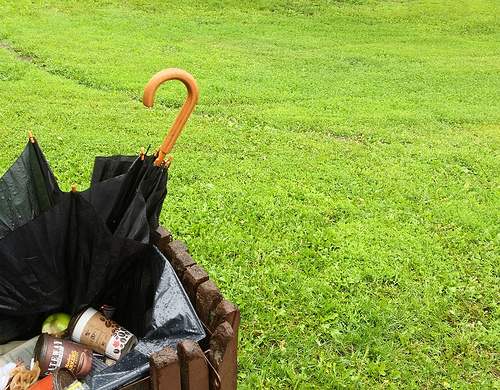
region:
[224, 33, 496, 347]
the grass is green and visible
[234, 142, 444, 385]
the grass is green and visible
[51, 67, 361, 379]
the grass is green and visible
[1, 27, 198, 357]
black umbrella with wooden handle in wooden trash bin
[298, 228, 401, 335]
patch of green grass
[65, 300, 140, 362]
empty cup of coffee in trash bin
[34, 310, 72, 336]
partially eaten green apple in trash bin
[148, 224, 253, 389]
corner of brown wooden trash bin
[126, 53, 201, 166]
brown wooden umbrella hook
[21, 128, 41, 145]
wood tip of umbrella spoke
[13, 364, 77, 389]
orange cup with brown lid in wooden trash bin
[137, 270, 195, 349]
black trash bag in brown wooden trash bin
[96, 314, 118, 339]
brown design on coffee cup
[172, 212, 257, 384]
edge of wood trash can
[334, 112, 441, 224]
neatly trimmed green grass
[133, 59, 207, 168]
wood handle of umbrella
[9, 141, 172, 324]
black material of umbrella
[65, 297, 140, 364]
paper cup in trash can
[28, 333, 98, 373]
coffee cup with lid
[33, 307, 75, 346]
green apple with bite missing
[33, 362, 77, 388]
orange cup in trash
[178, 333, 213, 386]
brown wood on trash can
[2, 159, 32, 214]
water drops on umbrella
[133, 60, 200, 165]
handle of an umbrella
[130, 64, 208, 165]
handle of umbrella is brown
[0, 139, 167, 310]
canopy of umbrella is fold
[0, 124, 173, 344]
canopy of umbrellas is black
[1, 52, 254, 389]
an umbrella on a trash can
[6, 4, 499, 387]
a trash can a green field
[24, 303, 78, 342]
an apple in the trash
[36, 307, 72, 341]
green apple is bitten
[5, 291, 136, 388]
trash in a trash can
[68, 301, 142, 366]
a coffee cup in the trash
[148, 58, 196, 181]
brown handle on umbrella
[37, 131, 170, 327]
umbrella is black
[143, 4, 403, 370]
grass is green and thick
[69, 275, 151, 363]
foam cup in bin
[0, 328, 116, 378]
brown cup in bin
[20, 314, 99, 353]
green apple in bin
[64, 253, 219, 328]
black bag in bin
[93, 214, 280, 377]
bin is wooden and brown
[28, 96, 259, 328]
umbrella in bin